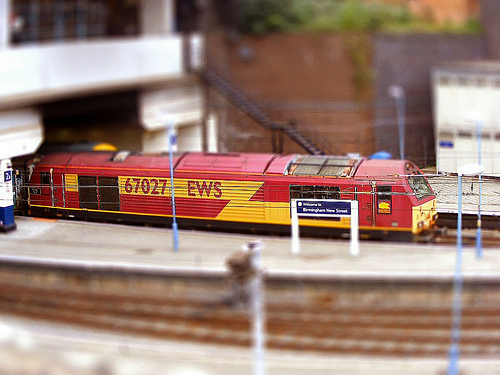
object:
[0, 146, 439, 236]
train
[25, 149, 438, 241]
train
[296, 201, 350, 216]
sign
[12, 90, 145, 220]
tunnel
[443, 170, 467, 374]
pole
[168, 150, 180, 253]
pole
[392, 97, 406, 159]
pole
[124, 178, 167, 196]
numbers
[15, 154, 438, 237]
toy train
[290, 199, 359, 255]
posts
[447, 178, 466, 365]
blue paint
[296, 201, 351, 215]
blue background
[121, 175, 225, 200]
red writing